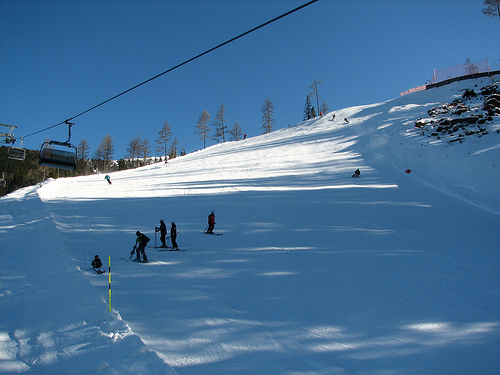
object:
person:
[104, 174, 112, 184]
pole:
[154, 226, 156, 246]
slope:
[0, 100, 500, 375]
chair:
[39, 122, 78, 171]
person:
[92, 254, 107, 274]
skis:
[159, 249, 187, 252]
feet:
[171, 246, 178, 248]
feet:
[160, 244, 167, 247]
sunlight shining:
[400, 314, 457, 334]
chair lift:
[2, 138, 26, 162]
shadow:
[287, 127, 371, 143]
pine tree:
[195, 111, 212, 149]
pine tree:
[210, 103, 229, 143]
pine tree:
[227, 121, 242, 141]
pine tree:
[260, 96, 274, 133]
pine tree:
[154, 120, 172, 162]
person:
[319, 111, 322, 117]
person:
[332, 113, 335, 119]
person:
[344, 117, 349, 123]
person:
[180, 151, 182, 156]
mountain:
[2, 65, 498, 367]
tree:
[95, 134, 114, 173]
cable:
[40, 0, 319, 131]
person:
[244, 134, 247, 139]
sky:
[38, 7, 473, 147]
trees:
[464, 58, 479, 79]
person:
[352, 168, 361, 178]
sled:
[91, 265, 107, 274]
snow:
[2, 67, 498, 368]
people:
[206, 210, 216, 234]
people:
[170, 221, 178, 250]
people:
[155, 219, 167, 247]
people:
[135, 230, 150, 263]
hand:
[155, 227, 158, 229]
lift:
[38, 120, 77, 171]